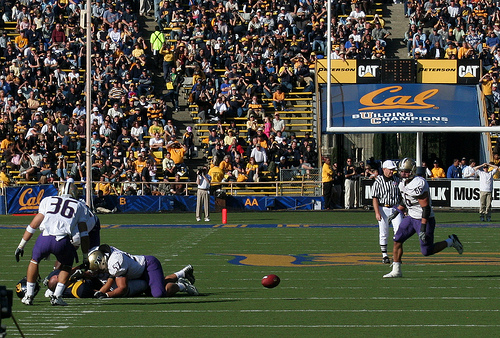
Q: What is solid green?
A: Football field.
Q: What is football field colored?
A: Green.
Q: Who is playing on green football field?
A: Players.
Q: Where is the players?
A: Green football field.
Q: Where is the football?
A: On green football field.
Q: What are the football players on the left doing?
A: Tackling each other.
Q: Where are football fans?
A: In the bleachers.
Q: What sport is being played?
A: Football.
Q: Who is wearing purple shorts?
A: Football players.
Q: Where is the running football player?
A: Next to the referee.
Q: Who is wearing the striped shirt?
A: The referee.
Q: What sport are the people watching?
A: Football.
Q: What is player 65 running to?
A: The football.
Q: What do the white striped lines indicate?
A: Yard lines.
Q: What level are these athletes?
A: College.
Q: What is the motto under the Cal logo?
A: Building Champions.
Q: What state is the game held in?
A: California.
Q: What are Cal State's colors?
A: Blue and gold.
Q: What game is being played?
A: Football.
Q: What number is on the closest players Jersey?
A: Thirty Six.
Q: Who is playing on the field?
A: Football players.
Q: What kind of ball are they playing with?
A: A football.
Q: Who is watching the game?
A: Spectators.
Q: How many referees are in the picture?
A: One.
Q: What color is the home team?
A: Blue and Yellow.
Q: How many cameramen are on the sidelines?
A: One.